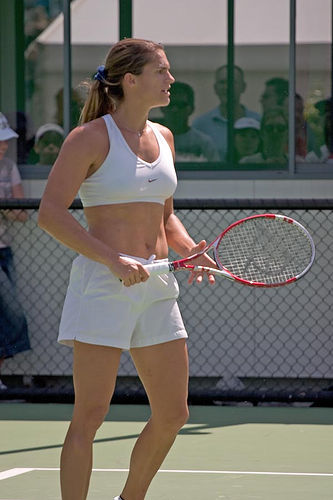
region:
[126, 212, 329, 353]
White and red tennis racket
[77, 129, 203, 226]
White and black spotrs bra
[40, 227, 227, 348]
Pait of white shorts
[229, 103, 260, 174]
People watching an event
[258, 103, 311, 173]
People watching an event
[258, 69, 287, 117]
People watching an event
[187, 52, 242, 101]
People watching an event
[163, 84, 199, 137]
People watching an event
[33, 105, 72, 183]
People watching an event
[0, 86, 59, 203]
People watching an event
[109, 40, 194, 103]
face of the girl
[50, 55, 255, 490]
a beautiful young girl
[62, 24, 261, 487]
a cute girl standing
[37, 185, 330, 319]
a girl holding bat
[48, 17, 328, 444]
a white girl ready to play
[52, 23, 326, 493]
a girl ready to play shuttle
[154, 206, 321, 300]
a small strong bat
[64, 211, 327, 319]
a badminton bat holding by girl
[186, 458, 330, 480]
a white line in ground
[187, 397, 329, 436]
shadow falling in ground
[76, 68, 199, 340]
this is a lady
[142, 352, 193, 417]
the lady is light skinned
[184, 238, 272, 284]
this is a racket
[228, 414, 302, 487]
this is the playing ground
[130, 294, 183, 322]
this is a short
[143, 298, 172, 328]
the short is white in color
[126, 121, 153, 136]
this is a necklace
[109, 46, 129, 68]
this is the hair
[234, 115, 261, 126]
this is a cap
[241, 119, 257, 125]
the cap is white in color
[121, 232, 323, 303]
A lady holding tennis racket.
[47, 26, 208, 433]
The tennis player is on the court.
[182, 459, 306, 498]
A white line on the court.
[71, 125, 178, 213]
The player is wearing a tubetop.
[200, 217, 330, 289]
The racket is red and blue.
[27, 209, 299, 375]
A fence around the court.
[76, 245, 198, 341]
The player is wearing white shorts.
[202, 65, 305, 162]
People watching the tennis match.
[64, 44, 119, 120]
The lady hair is in a ponytail.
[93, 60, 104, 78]
A blue bow in the hair.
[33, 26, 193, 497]
this is a tennis player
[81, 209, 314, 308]
she is holding a racket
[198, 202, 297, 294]
the racket is red in color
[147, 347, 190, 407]
this is the thigh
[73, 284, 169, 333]
she is wearing a short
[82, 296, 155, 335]
the short is white in color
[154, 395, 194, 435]
this is the knee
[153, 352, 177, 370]
the player is light skinned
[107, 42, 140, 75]
this is the hair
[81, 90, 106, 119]
the hair is long